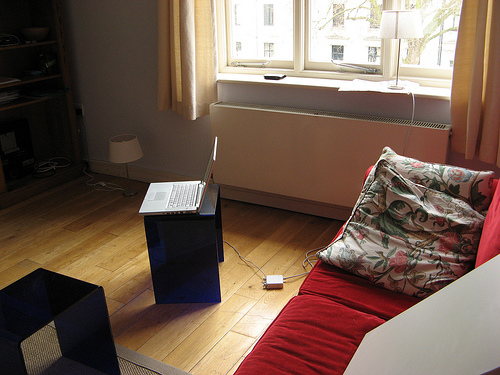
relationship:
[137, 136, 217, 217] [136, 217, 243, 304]
laptop on table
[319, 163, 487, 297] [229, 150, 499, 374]
pillow on couch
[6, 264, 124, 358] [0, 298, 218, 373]
stool on rug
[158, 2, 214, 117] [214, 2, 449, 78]
curtain next to window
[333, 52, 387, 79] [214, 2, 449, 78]
silver lever on window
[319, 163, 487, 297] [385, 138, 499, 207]
pillow leaning on pillow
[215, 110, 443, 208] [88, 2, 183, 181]
radiator on wall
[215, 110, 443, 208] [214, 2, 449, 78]
radiator under window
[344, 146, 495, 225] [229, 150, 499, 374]
pillow on couch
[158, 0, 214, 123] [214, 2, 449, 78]
curtain left of window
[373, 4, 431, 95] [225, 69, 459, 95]
lamp on windowsill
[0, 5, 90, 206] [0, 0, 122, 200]
entertainment center in corner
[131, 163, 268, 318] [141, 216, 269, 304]
laptop on table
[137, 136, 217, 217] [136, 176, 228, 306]
laptop on table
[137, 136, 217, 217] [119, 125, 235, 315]
laptop on top of table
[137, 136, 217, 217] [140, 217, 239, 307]
laptop on top of table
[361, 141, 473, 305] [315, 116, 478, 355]
pillows on sofa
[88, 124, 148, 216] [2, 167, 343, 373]
lamp on floor